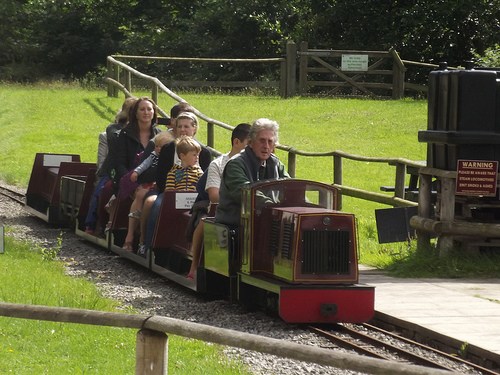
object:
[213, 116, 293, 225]
man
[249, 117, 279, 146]
hair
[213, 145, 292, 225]
jacket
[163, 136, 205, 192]
boy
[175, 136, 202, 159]
hair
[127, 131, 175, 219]
boy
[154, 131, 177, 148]
hair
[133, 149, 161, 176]
shirt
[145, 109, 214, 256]
woman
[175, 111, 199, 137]
hair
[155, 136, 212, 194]
jacket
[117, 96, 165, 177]
woman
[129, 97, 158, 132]
hair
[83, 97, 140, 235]
people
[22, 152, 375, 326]
train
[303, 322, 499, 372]
train tracks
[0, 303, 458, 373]
rail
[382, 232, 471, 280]
weed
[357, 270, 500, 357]
platform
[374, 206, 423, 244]
sign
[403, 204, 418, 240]
post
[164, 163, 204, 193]
sweater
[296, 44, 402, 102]
gate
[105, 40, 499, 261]
fence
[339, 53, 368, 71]
sign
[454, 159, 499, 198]
sign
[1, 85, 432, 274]
area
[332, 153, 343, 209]
fence post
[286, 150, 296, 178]
fence post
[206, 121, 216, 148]
fence post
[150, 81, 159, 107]
fence post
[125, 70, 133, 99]
fence post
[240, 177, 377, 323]
train engine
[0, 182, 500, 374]
gravel